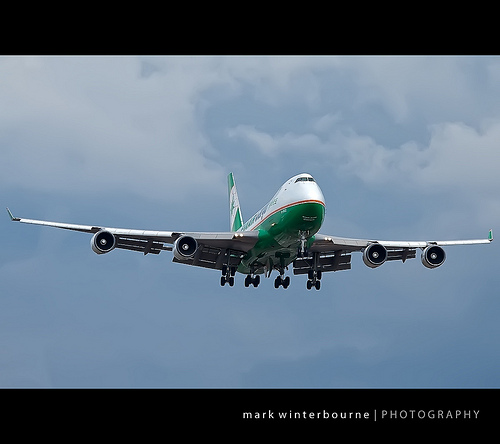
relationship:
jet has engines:
[6, 173, 495, 289] [89, 230, 446, 269]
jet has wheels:
[6, 173, 495, 289] [221, 265, 322, 290]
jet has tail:
[6, 173, 495, 289] [228, 171, 243, 234]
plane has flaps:
[6, 173, 495, 289] [116, 232, 416, 274]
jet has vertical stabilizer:
[6, 173, 495, 289] [228, 171, 243, 234]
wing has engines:
[6, 209, 259, 262] [90, 229, 198, 260]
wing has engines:
[299, 230, 494, 258] [362, 243, 446, 268]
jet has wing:
[6, 173, 495, 289] [6, 209, 259, 262]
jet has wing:
[6, 173, 495, 289] [299, 230, 494, 258]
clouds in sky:
[1, 57, 497, 247] [1, 55, 499, 389]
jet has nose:
[6, 173, 495, 289] [266, 182, 326, 232]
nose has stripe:
[266, 182, 326, 232] [245, 199, 325, 230]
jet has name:
[6, 173, 495, 289] [237, 203, 272, 231]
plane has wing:
[6, 173, 495, 289] [4, 206, 260, 262]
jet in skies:
[6, 173, 495, 289] [1, 55, 499, 389]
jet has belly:
[6, 173, 495, 289] [236, 202, 325, 273]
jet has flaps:
[6, 173, 495, 289] [116, 232, 416, 274]